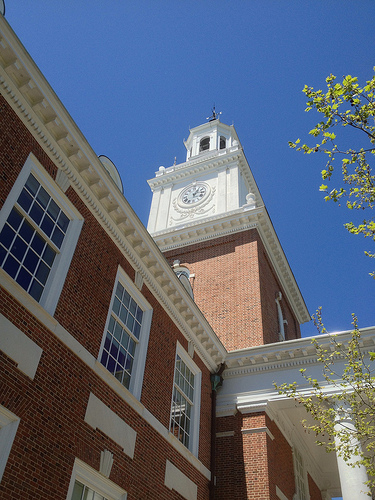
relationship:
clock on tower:
[180, 184, 207, 205] [145, 105, 314, 353]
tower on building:
[145, 105, 314, 353] [1, 2, 373, 500]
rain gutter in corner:
[210, 363, 226, 500] [213, 374, 216, 497]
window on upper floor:
[1, 150, 87, 319] [3, 92, 214, 483]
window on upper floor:
[95, 263, 154, 404] [3, 92, 214, 483]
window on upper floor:
[166, 337, 203, 461] [3, 92, 214, 483]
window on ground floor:
[64, 455, 129, 499] [1, 282, 216, 500]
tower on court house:
[145, 105, 314, 353] [1, 2, 373, 500]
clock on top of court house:
[180, 184, 207, 205] [1, 2, 373, 500]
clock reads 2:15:
[180, 184, 207, 205] [190, 186, 206, 198]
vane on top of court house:
[205, 103, 223, 126] [1, 2, 373, 500]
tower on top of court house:
[145, 105, 314, 353] [1, 2, 373, 500]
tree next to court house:
[285, 68, 374, 498] [1, 2, 373, 500]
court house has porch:
[1, 2, 373, 500] [214, 324, 374, 500]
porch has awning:
[214, 324, 374, 500] [212, 325, 374, 418]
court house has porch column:
[1, 2, 373, 500] [324, 393, 372, 500]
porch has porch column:
[214, 324, 374, 500] [324, 393, 372, 500]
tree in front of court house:
[285, 68, 374, 498] [1, 2, 373, 500]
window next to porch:
[166, 337, 203, 461] [214, 324, 374, 500]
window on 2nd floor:
[166, 337, 203, 461] [3, 92, 214, 483]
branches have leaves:
[285, 68, 374, 498] [333, 70, 363, 106]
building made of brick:
[1, 2, 373, 500] [249, 448, 255, 451]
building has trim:
[1, 2, 373, 500] [147, 204, 314, 328]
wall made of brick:
[1, 92, 216, 498] [249, 448, 255, 451]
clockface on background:
[180, 184, 207, 205] [175, 179, 214, 211]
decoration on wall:
[239, 425, 275, 443] [1, 92, 216, 498]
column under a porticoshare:
[324, 393, 372, 500] [214, 324, 374, 500]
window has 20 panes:
[1, 150, 87, 319] [1, 171, 74, 306]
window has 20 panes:
[95, 263, 154, 404] [99, 279, 147, 397]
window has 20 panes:
[166, 337, 203, 461] [167, 352, 197, 451]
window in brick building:
[166, 337, 203, 461] [1, 2, 373, 500]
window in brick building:
[1, 150, 87, 319] [1, 2, 373, 500]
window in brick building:
[95, 263, 154, 404] [1, 2, 373, 500]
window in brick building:
[64, 455, 129, 499] [1, 2, 373, 500]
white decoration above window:
[52, 164, 75, 194] [1, 150, 87, 319]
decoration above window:
[133, 269, 147, 293] [95, 263, 154, 404]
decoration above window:
[184, 341, 200, 358] [166, 337, 203, 461]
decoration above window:
[97, 449, 117, 479] [64, 455, 129, 499]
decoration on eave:
[243, 188, 259, 211] [232, 206, 272, 238]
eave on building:
[232, 206, 272, 238] [1, 2, 373, 500]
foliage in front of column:
[271, 302, 374, 498] [324, 393, 372, 500]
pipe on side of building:
[210, 390, 217, 499] [1, 2, 373, 500]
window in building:
[96, 153, 125, 197] [1, 2, 373, 500]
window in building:
[175, 273, 195, 302] [1, 2, 373, 500]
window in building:
[273, 298, 287, 343] [1, 2, 373, 500]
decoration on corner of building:
[239, 425, 275, 443] [1, 2, 373, 500]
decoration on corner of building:
[243, 188, 259, 211] [1, 2, 373, 500]